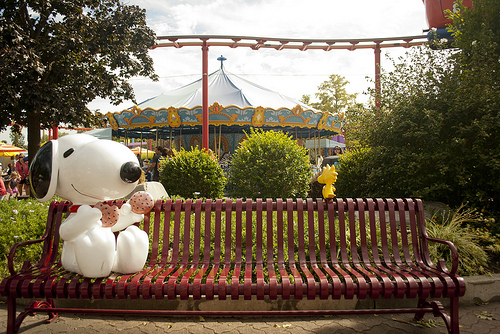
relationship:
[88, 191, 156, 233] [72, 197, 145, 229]
cookies in hands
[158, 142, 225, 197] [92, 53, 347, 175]
bush in front of carousel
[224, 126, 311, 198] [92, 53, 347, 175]
bush in front of carousel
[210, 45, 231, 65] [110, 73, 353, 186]
cross on top of carousel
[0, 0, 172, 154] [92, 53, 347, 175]
tree to left of carousel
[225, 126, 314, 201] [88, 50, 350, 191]
bush in front of carousel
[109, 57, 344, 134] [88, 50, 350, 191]
tent of carousel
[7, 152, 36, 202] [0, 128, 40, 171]
people near tent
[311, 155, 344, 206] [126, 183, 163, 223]
statue holding cookie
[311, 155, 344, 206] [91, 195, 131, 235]
statue holding cookie